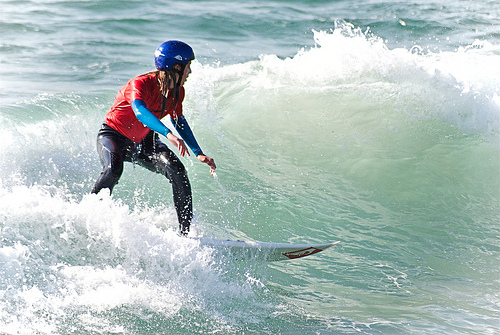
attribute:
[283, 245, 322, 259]
logo — red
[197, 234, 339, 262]
surfboard — white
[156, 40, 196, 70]
helmet — blue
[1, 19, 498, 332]
wave — blue green, splashing, blue, white, sloped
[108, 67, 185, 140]
t-shirt — red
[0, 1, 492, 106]
water — calm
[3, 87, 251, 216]
water — smooth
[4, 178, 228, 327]
water — rough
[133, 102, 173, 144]
sleeve — blue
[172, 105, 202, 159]
sleeve — blue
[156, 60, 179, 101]
hair — long, wet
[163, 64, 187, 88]
strap — black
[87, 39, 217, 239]
woman — young, surfing, wet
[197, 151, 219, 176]
hand — surfer's 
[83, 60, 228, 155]
shirt — red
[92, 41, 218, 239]
surfer — red, blue, black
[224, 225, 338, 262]
surfboard — white, red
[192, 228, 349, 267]
surfboard — white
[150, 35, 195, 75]
helmet — blue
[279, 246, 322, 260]
logo — red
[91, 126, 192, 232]
pants — black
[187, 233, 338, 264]
board — red, white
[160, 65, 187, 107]
sticks — wet, hair, brown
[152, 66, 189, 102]
neck — surfer